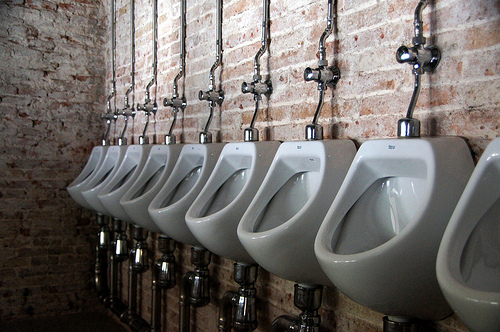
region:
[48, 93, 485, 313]
row of white urinals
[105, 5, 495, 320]
brick wall urinals are attached to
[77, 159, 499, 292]
bowls of white urinals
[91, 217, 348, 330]
silver pipes running from the floor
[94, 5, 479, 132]
pipes attached to tops of urinals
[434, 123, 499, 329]
first urinal in the row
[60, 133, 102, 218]
urinal against background wall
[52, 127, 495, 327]
nine white urinals against brick wall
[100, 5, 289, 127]
patch of sunlight on the wall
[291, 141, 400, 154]
black printing on two urinals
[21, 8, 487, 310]
photograph of a men's bathroom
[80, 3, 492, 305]
white urinals along a red brick wall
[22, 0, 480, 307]
red brick wall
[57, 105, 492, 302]
row of 9 white urinals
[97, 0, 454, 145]
silver piping above urinals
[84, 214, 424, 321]
silver plumbing below urinals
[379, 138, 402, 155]
black lettering on white urinals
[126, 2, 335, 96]
light shining on brick wall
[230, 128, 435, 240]
light shining on urinals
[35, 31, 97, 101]
cracks in red brick wal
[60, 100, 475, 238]
line of urinals in bathroom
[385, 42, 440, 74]
silver handle on urnal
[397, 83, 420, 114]
silver pipe of urinal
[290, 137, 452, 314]
white base of urinal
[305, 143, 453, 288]
white bowl of urinal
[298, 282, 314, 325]
silver piping beneath toilet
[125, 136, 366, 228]
line of toilets on the wall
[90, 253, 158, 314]
connected silver piping of toielts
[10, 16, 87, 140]
faded brick wall on side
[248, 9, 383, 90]
white and orange brick wall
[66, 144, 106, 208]
white ceramic urinal on a brick wall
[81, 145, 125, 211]
white ceramic urinal on a brick wall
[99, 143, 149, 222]
white ceramic urinal on a brick wall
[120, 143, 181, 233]
white ceramic urinal on a brick wall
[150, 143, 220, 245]
white ceramic urinal on a brick wall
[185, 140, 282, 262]
white ceramic urinal on a brick wall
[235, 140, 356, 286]
white ceramic urinal on a brick wall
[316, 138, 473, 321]
white ceramic urinal on a brick wall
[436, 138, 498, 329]
part of white ceramic urinal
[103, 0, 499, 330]
brick wall with urinals on it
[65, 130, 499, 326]
a line of urinals in the bathroom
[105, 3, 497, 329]
the brick wall the urinals are attached too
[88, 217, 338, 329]
the pipes underneath the urinals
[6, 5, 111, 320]
the other brick wall in the bathroom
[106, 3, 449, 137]
the pipes above all the urinal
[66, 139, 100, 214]
the urinal closest to the corner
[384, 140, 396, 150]
the name of the company in the corner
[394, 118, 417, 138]
the part that attaches the pole to the urinal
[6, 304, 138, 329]
the floor of the bathroom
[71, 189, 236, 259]
the bottom part of some of the urinals